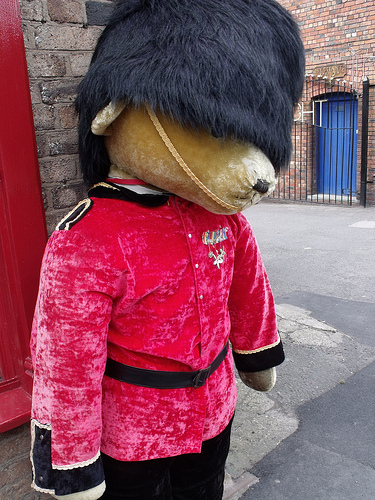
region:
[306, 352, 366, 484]
mixed stone pavement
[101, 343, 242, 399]
black belt on a teddy bear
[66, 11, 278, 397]
teddy bear dressed like the royal guard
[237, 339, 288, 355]
gold trim on the cuff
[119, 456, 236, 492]
black pants on a teddy bear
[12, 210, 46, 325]
red door behind the bear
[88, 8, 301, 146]
black hat on a teddy bear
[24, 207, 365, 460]
red jacket on a teddy bear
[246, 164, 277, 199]
brown nose on the teddy bear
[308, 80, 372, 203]
blue door behind bars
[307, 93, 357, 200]
Blue Door on the buidling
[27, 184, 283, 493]
Red Velvet Jacket on the bear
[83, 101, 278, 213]
Bear head that is brown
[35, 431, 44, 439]
Snap on the jacket cuff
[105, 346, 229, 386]
Black belt on the bear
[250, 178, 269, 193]
Brown nose of a bear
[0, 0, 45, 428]
Red glossy door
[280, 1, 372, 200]
Tall brick building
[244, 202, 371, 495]
Street that is paved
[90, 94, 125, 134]
Ear of a bear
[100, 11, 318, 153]
A black hairly hood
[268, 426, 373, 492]
A black tarmac road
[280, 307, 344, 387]
A grey tarmac road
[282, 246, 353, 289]
A grey tarmac road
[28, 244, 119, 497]
An arm of a statue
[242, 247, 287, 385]
An arm of a statue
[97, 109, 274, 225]
A brown statue dog face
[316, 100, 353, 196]
A blue wooden door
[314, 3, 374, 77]
A brick house wall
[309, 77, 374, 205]
A metalic pole gate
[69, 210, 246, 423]
Teddy bear wearing red jacket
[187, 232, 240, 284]
medals on a teddy bear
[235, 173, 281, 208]
teddy bear with a black nose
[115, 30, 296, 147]
teddy bear with a black hat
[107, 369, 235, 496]
teddy bear wearing black pants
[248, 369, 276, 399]
teddy bear with brown paws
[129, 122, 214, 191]
teddy bear with a brown face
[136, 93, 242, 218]
Teddy bear with a strap across the face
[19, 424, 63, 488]
buttons on the sleeve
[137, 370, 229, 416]
belts on the teddy bear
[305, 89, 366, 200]
blue door on brick building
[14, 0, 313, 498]
life siized teddy bear in uniform on a sidewalk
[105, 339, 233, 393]
black belt wiith plastic clasp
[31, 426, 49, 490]
metal buttons on side of coat cuff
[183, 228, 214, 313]
three buttons on front of a red and black jacket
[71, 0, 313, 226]
black fur hat with chin strap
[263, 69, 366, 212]
black fence in front of blue door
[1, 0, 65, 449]
red door on side of brick wall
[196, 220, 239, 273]
military stripes on front of red and black coat